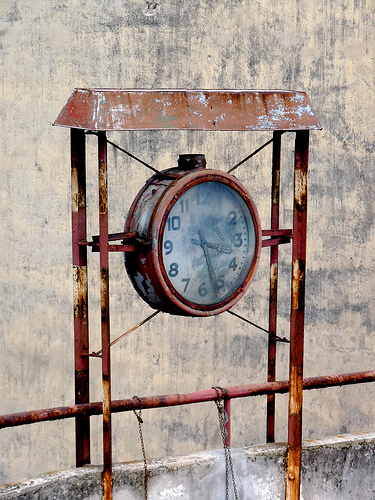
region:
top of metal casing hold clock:
[47, 73, 335, 160]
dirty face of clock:
[163, 171, 256, 314]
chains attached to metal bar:
[124, 378, 261, 499]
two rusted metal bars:
[264, 226, 314, 406]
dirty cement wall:
[18, 218, 62, 388]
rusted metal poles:
[48, 309, 147, 498]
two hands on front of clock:
[189, 219, 238, 297]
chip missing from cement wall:
[129, 0, 190, 31]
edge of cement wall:
[303, 414, 372, 485]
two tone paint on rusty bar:
[62, 251, 97, 319]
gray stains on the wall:
[318, 256, 372, 323]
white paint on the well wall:
[156, 480, 200, 497]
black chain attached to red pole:
[127, 388, 154, 429]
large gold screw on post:
[263, 456, 308, 488]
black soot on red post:
[113, 386, 178, 413]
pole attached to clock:
[76, 300, 211, 376]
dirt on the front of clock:
[184, 212, 235, 281]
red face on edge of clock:
[127, 169, 267, 323]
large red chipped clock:
[119, 148, 284, 308]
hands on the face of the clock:
[186, 230, 239, 283]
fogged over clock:
[130, 148, 271, 330]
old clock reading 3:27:
[126, 150, 259, 322]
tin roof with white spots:
[56, 75, 319, 136]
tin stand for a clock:
[48, 68, 341, 485]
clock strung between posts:
[73, 133, 319, 375]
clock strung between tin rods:
[48, 67, 356, 447]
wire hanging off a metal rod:
[126, 382, 246, 497]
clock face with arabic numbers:
[160, 169, 257, 312]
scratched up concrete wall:
[64, 31, 266, 55]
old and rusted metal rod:
[289, 131, 313, 498]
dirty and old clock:
[121, 147, 268, 318]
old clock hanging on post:
[125, 154, 263, 319]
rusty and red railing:
[0, 361, 374, 436]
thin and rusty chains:
[118, 377, 262, 499]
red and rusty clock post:
[50, 78, 309, 498]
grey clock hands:
[188, 223, 236, 301]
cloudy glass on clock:
[163, 174, 259, 308]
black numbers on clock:
[162, 185, 254, 305]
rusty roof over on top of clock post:
[51, 80, 327, 140]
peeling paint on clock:
[119, 150, 174, 315]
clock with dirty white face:
[157, 183, 253, 307]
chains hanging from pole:
[130, 388, 246, 495]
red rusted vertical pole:
[287, 316, 305, 427]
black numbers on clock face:
[161, 240, 192, 296]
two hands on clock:
[188, 228, 239, 294]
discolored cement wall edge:
[307, 438, 363, 491]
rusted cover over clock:
[57, 77, 322, 145]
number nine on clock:
[158, 237, 184, 264]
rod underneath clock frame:
[225, 306, 278, 338]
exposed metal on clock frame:
[134, 265, 155, 310]